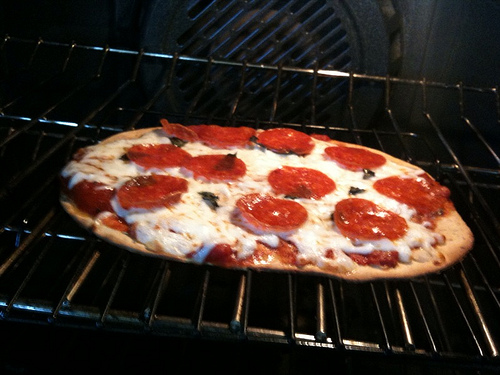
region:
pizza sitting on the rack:
[58, 105, 491, 305]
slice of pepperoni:
[236, 190, 311, 232]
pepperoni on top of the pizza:
[58, 127, 458, 283]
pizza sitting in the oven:
[1, 2, 493, 371]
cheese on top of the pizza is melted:
[56, 104, 469, 292]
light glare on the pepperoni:
[370, 210, 385, 216]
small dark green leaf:
[196, 190, 221, 210]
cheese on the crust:
[427, 231, 453, 266]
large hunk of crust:
[431, 215, 473, 253]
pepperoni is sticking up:
[158, 115, 193, 147]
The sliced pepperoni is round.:
[196, 117, 258, 154]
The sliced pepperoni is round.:
[253, 120, 319, 157]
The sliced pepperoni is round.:
[322, 138, 389, 176]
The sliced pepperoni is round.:
[373, 165, 448, 222]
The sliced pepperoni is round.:
[326, 190, 411, 247]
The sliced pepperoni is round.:
[265, 158, 338, 202]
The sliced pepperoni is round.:
[237, 188, 312, 238]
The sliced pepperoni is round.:
[183, 149, 248, 182]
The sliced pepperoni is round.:
[115, 169, 192, 214]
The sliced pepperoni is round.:
[118, 135, 196, 177]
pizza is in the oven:
[92, 54, 493, 326]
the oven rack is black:
[75, 265, 400, 368]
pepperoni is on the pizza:
[152, 161, 494, 348]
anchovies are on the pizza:
[111, 131, 468, 322]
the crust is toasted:
[285, 194, 460, 259]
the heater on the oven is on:
[192, 3, 462, 101]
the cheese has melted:
[127, 88, 482, 370]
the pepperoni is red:
[91, 103, 421, 293]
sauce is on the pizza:
[217, 219, 390, 344]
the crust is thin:
[77, 149, 273, 366]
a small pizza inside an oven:
[64, 120, 476, 280]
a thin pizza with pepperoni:
[63, 121, 473, 280]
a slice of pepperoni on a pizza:
[268, 163, 333, 199]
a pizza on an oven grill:
[63, 118, 473, 283]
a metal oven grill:
[0, 32, 499, 370]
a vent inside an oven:
[143, 4, 388, 144]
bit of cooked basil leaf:
[168, 135, 185, 147]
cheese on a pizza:
[60, 128, 442, 265]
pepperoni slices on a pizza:
[63, 119, 475, 276]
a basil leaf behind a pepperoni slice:
[217, 153, 238, 173]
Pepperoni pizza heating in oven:
[52, 111, 472, 286]